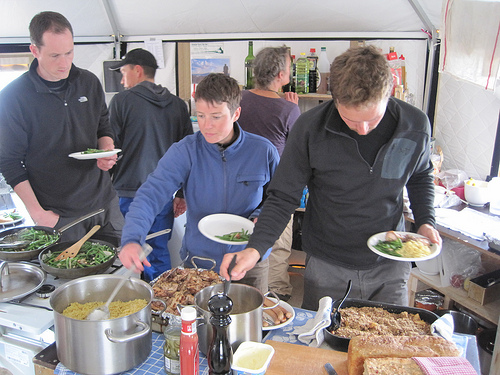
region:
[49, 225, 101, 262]
A wooden kitchen utensil.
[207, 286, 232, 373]
A black pepper grinder.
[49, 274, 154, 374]
A large silver pot with handles.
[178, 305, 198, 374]
A red plastic bottle with a white lid.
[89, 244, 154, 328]
A silver metal serving spoon.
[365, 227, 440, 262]
A white round plate of food.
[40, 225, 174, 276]
A dark grey frying pan.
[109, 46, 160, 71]
A black ball cap.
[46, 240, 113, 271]
Cooked green beans.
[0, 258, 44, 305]
A silver lid to a pot.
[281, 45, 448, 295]
guy with short brown hair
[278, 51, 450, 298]
guy wearing black sweater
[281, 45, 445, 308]
guy holding plate full of food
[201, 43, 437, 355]
guy getting food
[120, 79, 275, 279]
lady wearing blue sweater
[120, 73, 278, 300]
lady holding plate of food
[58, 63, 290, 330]
lady getting food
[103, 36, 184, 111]
guy wearing a baseball cap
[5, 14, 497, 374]
People putting food on there plate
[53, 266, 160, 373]
pot of food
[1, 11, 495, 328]
group of people getting food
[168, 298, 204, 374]
ketchup bottle on the table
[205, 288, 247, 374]
a black pepper grinder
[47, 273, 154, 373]
a silver pot of food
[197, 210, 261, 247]
a white plate with green beans on it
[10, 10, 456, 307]
four people wearing grey shirts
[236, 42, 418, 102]
person looking at food on the shelf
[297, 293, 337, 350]
white towel leaning on a black pan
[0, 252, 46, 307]
silver lid to a pot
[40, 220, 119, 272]
wood spoon in a pan of salad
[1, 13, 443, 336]
people standing in line at a buffet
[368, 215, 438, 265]
man holding a white plate with food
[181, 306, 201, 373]
a bottle of ketchup on a table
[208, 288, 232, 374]
a black pepper grinder on a table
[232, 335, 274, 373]
a plastic container of margerine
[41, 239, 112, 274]
green beans in a black pan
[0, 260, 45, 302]
stainless steel lid of a pot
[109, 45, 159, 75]
man wearing a black cap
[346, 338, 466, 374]
a loaf of bread on a table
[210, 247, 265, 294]
a man holding a laddle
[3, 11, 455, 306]
A group of people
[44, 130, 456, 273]
People are holding a plate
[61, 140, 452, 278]
Plates are white in color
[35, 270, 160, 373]
A pot is in the foreground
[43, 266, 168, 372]
The pot is silver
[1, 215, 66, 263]
A black flying pan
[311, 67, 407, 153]
Man has his head down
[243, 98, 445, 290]
Man is wearing a black shirt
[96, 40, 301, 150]
Two people in the background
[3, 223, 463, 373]
Food is on the table